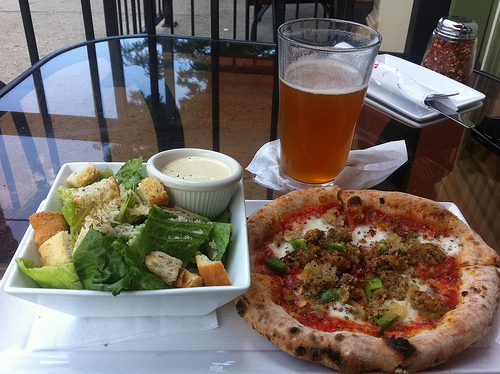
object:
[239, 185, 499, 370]
pizza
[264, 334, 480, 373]
crust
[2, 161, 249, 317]
bowl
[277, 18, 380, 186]
glass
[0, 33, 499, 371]
table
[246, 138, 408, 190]
napkin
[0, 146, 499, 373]
meal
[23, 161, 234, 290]
salad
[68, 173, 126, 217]
croutons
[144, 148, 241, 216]
bowl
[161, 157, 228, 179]
dressing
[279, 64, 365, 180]
beverage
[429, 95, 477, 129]
silverwarre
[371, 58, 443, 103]
napkin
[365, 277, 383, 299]
pepper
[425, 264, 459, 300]
sauce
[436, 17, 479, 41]
lid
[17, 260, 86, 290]
lettuce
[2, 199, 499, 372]
plate